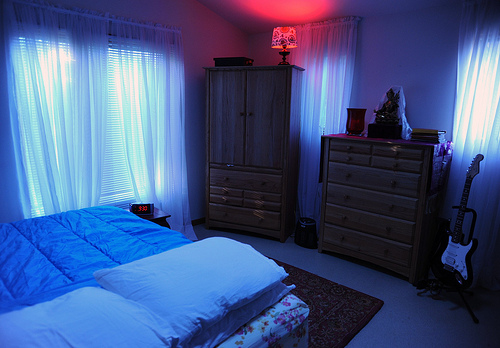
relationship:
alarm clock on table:
[129, 202, 155, 218] [129, 196, 170, 224]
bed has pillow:
[1, 200, 313, 347] [0, 284, 181, 343]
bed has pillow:
[1, 200, 313, 347] [0, 237, 289, 348]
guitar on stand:
[433, 152, 490, 287] [419, 202, 481, 326]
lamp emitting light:
[268, 22, 301, 67] [238, 2, 339, 27]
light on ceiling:
[238, 2, 339, 27] [199, 0, 496, 43]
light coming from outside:
[19, 38, 499, 214] [20, 19, 499, 214]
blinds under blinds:
[16, 25, 499, 196] [0, 0, 500, 292]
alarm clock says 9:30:
[129, 202, 155, 218] [135, 203, 148, 211]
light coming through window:
[19, 38, 499, 214] [19, 49, 169, 205]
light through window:
[19, 38, 499, 214] [19, 49, 169, 205]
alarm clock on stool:
[129, 202, 155, 218] [125, 197, 171, 232]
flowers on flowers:
[225, 296, 314, 346] [217, 292, 311, 348]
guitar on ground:
[433, 152, 490, 287] [187, 221, 499, 347]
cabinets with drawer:
[317, 133, 453, 288] [326, 182, 418, 221]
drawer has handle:
[318, 183, 421, 219] [343, 192, 353, 202]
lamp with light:
[268, 22, 301, 67] [238, 2, 339, 27]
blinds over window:
[0, 0, 500, 292] [19, 49, 169, 205]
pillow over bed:
[0, 284, 181, 343] [1, 200, 313, 347]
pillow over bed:
[0, 237, 289, 348] [1, 200, 313, 347]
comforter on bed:
[3, 200, 196, 311] [1, 200, 313, 347]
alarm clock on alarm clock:
[125, 199, 154, 216] [129, 202, 155, 218]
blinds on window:
[0, 0, 500, 292] [19, 49, 169, 205]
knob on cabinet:
[248, 111, 255, 118] [199, 58, 305, 241]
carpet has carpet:
[265, 255, 385, 348] [265, 255, 385, 348]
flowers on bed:
[217, 292, 311, 348] [1, 200, 313, 347]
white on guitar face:
[442, 239, 474, 279] [431, 222, 478, 293]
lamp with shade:
[268, 22, 301, 67] [272, 26, 299, 47]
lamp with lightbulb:
[268, 22, 301, 67] [281, 43, 289, 48]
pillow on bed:
[0, 284, 181, 343] [1, 200, 313, 347]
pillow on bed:
[0, 237, 289, 348] [1, 200, 313, 347]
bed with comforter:
[1, 200, 313, 347] [3, 200, 196, 311]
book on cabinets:
[412, 128, 447, 134] [317, 133, 453, 288]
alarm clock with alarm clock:
[125, 199, 154, 216] [129, 202, 155, 218]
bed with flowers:
[1, 200, 313, 347] [217, 292, 311, 348]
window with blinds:
[19, 49, 169, 205] [17, 41, 168, 208]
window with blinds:
[19, 49, 169, 205] [0, 0, 500, 292]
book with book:
[412, 128, 447, 134] [412, 127, 449, 133]